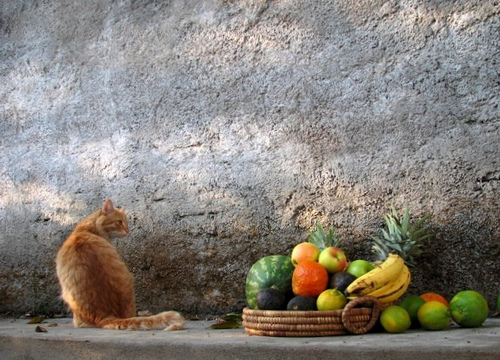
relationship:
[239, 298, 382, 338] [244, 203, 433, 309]
basket of fruit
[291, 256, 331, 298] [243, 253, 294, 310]
orange beside watermellow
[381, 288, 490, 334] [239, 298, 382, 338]
limes near basket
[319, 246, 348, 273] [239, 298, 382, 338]
apple in basket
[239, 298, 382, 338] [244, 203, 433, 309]
basket holding fruit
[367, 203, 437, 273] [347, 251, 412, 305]
pineapple behins bananas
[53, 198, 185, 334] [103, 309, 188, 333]
cat has tail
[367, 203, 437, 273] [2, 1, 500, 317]
pineapple against wall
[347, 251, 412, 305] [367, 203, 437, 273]
bananas near pineapple